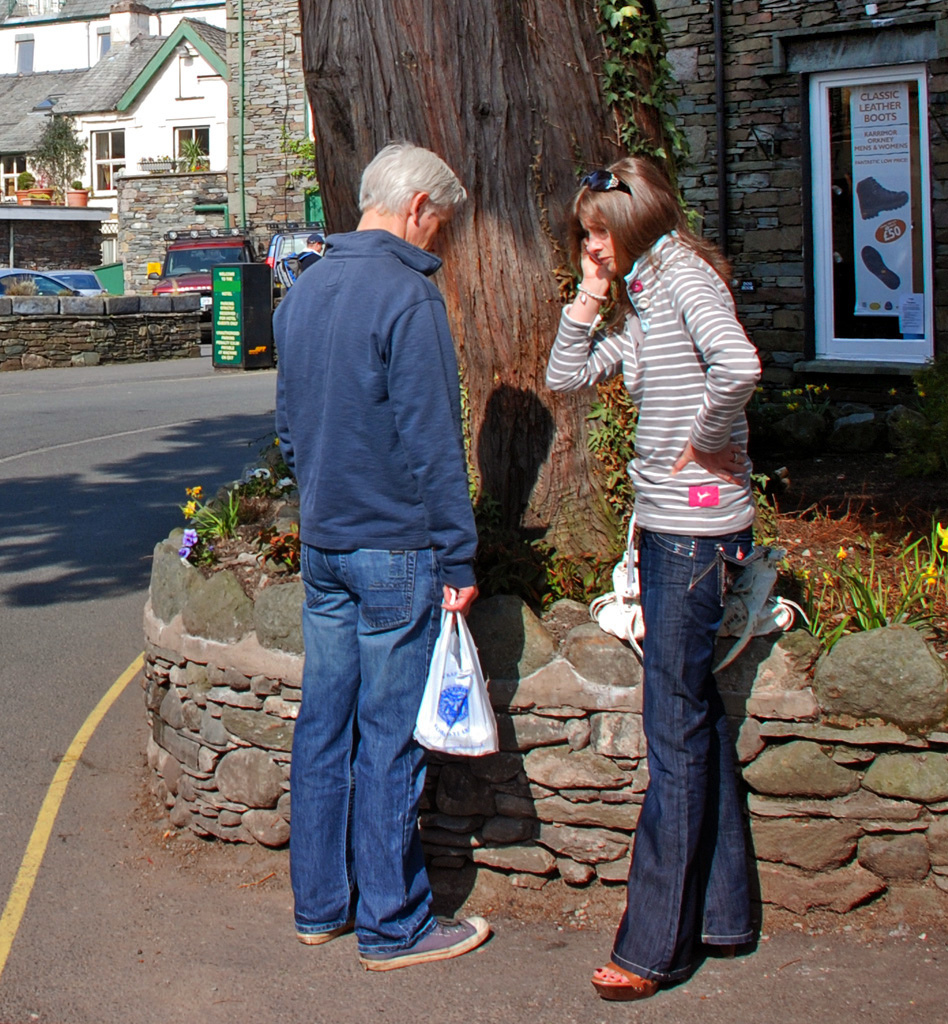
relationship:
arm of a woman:
[546, 295, 635, 388] [543, 174, 801, 1018]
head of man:
[351, 140, 469, 255] [259, 137, 496, 969]